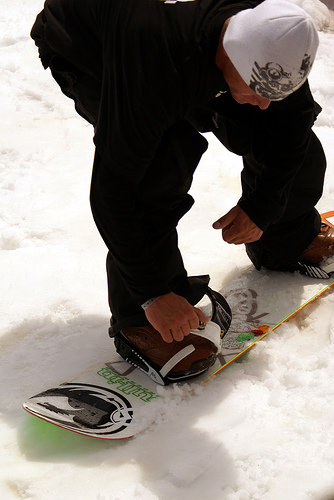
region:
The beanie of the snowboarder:
[222, 0, 323, 103]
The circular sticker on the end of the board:
[21, 380, 138, 442]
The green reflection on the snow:
[15, 407, 116, 457]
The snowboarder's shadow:
[0, 313, 245, 497]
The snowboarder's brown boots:
[123, 222, 333, 370]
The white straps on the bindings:
[158, 315, 221, 377]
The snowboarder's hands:
[137, 205, 267, 347]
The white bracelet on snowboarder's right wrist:
[137, 291, 158, 311]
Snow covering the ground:
[0, 1, 333, 497]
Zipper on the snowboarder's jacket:
[212, 84, 232, 104]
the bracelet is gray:
[136, 278, 175, 315]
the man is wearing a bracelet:
[129, 274, 202, 333]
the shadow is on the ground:
[18, 309, 225, 496]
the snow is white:
[252, 423, 296, 480]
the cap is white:
[234, 16, 315, 108]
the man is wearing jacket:
[36, 7, 274, 233]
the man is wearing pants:
[45, 13, 302, 258]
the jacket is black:
[45, 8, 301, 302]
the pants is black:
[42, 62, 315, 299]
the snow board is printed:
[16, 316, 254, 465]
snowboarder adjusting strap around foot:
[72, 10, 315, 446]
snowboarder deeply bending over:
[25, 7, 311, 293]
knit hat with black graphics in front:
[215, 0, 328, 105]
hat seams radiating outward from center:
[219, 0, 322, 86]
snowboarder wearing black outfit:
[21, 5, 314, 285]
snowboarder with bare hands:
[102, 206, 285, 350]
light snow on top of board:
[203, 265, 303, 359]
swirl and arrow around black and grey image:
[19, 373, 138, 452]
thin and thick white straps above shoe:
[124, 309, 247, 384]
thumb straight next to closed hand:
[204, 193, 272, 259]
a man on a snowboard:
[21, 1, 332, 442]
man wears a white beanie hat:
[215, 0, 322, 106]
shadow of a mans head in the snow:
[130, 420, 239, 498]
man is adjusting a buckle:
[109, 283, 222, 354]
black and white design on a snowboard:
[17, 374, 138, 436]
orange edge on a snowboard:
[16, 268, 329, 438]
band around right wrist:
[137, 288, 174, 306]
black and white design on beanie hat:
[238, 40, 311, 100]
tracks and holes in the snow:
[175, 334, 322, 494]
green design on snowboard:
[95, 361, 161, 401]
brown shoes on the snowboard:
[109, 295, 221, 390]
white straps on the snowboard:
[139, 337, 196, 377]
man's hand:
[133, 288, 227, 343]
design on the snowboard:
[29, 358, 154, 443]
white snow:
[231, 382, 323, 478]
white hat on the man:
[220, 0, 325, 99]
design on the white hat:
[250, 43, 320, 104]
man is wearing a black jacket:
[24, 2, 333, 221]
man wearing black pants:
[38, 46, 322, 322]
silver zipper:
[211, 85, 229, 105]